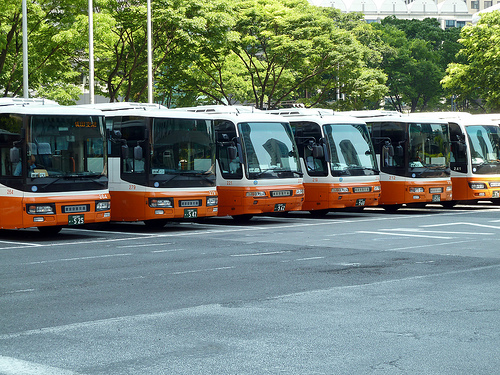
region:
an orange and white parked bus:
[1, 96, 108, 235]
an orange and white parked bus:
[87, 98, 218, 232]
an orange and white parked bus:
[186, 103, 306, 222]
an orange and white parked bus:
[269, 107, 382, 214]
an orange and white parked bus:
[349, 111, 452, 214]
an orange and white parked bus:
[414, 111, 499, 207]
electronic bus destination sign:
[71, 116, 101, 129]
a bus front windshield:
[28, 117, 107, 178]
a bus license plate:
[67, 212, 84, 224]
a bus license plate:
[182, 207, 199, 219]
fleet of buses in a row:
[6, 78, 496, 233]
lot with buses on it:
[20, 252, 482, 352]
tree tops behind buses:
[7, 5, 493, 104]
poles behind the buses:
[12, 12, 160, 94]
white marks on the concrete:
[339, 220, 494, 252]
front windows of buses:
[26, 118, 497, 175]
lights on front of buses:
[24, 179, 499, 211]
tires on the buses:
[31, 198, 497, 236]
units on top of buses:
[3, 85, 497, 120]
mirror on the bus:
[115, 131, 125, 145]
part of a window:
[265, 127, 291, 166]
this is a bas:
[218, 115, 299, 207]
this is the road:
[278, 235, 362, 285]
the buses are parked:
[214, 124, 270, 219]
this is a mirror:
[227, 142, 240, 160]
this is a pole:
[145, 13, 169, 94]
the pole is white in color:
[143, 16, 159, 56]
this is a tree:
[241, 26, 359, 75]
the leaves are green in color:
[274, 38, 327, 74]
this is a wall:
[406, 3, 468, 18]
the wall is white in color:
[431, 3, 459, 16]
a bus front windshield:
[152, 118, 212, 183]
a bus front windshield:
[240, 121, 295, 176]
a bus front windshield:
[324, 124, 375, 171]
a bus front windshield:
[409, 121, 451, 176]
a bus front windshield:
[466, 124, 498, 174]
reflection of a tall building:
[261, 138, 289, 168]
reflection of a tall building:
[339, 137, 362, 174]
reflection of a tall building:
[475, 128, 490, 160]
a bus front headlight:
[34, 205, 49, 213]